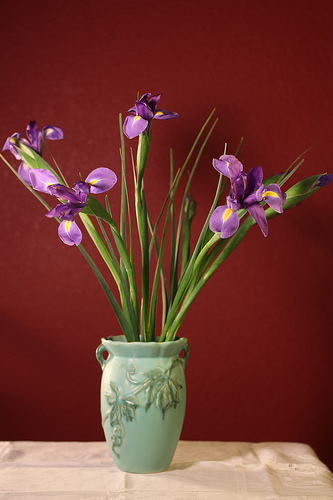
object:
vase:
[93, 333, 187, 475]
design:
[145, 369, 182, 421]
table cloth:
[1, 438, 332, 498]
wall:
[0, 2, 331, 441]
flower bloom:
[28, 162, 117, 250]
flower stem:
[132, 125, 156, 341]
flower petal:
[121, 115, 148, 140]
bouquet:
[156, 150, 286, 345]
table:
[0, 438, 332, 500]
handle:
[95, 343, 110, 368]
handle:
[177, 340, 192, 363]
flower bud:
[232, 180, 264, 205]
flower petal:
[154, 109, 175, 122]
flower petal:
[85, 166, 117, 194]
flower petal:
[212, 153, 242, 180]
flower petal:
[208, 204, 238, 240]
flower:
[0, 119, 63, 188]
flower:
[260, 173, 333, 219]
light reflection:
[94, 336, 146, 472]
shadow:
[141, 431, 252, 471]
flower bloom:
[122, 90, 178, 184]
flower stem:
[85, 198, 139, 345]